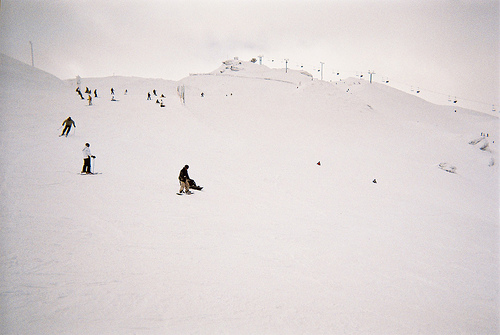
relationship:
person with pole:
[60, 116, 77, 136] [57, 122, 64, 131]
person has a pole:
[60, 116, 77, 136] [57, 122, 64, 131]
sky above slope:
[2, 2, 499, 118] [0, 59, 498, 335]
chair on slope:
[451, 96, 460, 106] [0, 59, 498, 335]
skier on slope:
[146, 92, 152, 100] [0, 59, 498, 335]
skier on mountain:
[146, 92, 152, 100] [1, 55, 498, 333]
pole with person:
[57, 122, 64, 131] [60, 116, 77, 136]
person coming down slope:
[60, 116, 77, 136] [0, 59, 498, 335]